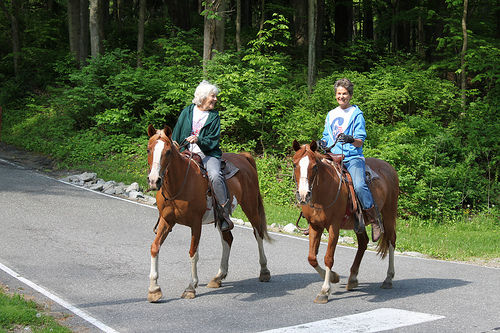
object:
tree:
[424, 0, 500, 151]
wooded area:
[0, 0, 500, 154]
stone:
[66, 171, 97, 182]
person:
[319, 77, 385, 242]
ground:
[0, 162, 500, 333]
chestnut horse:
[140, 128, 278, 302]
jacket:
[319, 104, 368, 161]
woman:
[168, 77, 236, 232]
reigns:
[315, 132, 355, 210]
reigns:
[168, 137, 197, 201]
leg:
[310, 222, 341, 305]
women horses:
[144, 77, 401, 305]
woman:
[326, 77, 376, 287]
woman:
[171, 70, 241, 266]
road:
[0, 153, 500, 332]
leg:
[345, 222, 370, 291]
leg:
[381, 216, 398, 287]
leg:
[305, 228, 340, 284]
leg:
[179, 222, 202, 301]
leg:
[146, 217, 173, 302]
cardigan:
[168, 106, 222, 159]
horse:
[141, 127, 273, 303]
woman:
[286, 74, 414, 299]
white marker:
[257, 306, 448, 333]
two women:
[163, 75, 387, 245]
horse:
[290, 136, 401, 305]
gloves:
[337, 133, 356, 145]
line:
[0, 264, 117, 333]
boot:
[363, 204, 385, 242]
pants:
[201, 153, 227, 211]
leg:
[207, 213, 235, 288]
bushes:
[63, 72, 155, 131]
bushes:
[385, 75, 500, 140]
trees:
[307, 0, 317, 91]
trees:
[86, 1, 101, 61]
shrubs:
[413, 0, 500, 102]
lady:
[166, 79, 235, 232]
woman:
[145, 72, 273, 299]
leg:
[244, 198, 273, 283]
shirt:
[321, 106, 367, 154]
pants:
[343, 156, 374, 209]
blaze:
[148, 140, 165, 181]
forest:
[1, 0, 500, 264]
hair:
[191, 80, 220, 106]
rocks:
[123, 182, 140, 198]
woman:
[319, 78, 388, 243]